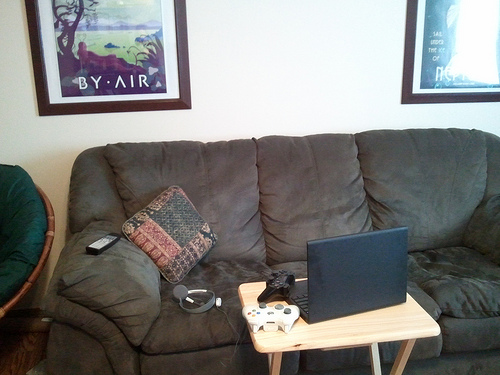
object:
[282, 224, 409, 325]
laptop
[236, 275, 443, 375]
table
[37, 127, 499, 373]
couch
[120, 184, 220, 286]
pillow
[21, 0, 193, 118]
painting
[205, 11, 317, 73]
wall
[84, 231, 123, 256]
remote control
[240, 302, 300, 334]
controllers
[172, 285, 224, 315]
headphones